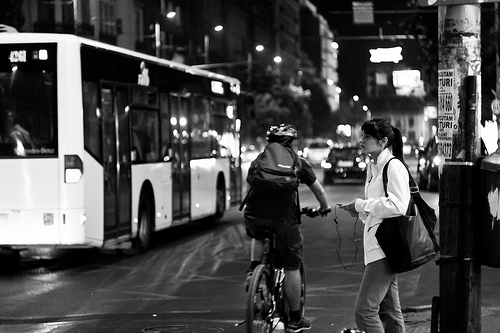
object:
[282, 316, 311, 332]
shoe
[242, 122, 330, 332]
bicyclist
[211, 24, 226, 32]
light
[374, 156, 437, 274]
bag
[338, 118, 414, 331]
girl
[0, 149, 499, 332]
street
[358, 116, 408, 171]
hair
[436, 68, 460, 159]
poster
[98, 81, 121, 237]
door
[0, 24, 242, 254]
bus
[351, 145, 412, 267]
shirt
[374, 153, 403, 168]
shoulder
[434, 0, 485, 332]
pole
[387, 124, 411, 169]
ponytail